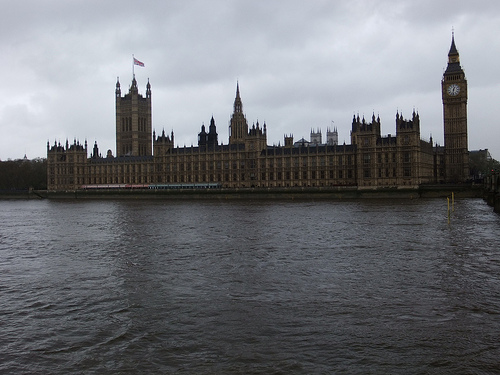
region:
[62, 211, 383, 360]
a body of water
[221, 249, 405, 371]
a body of calm water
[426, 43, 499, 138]
an outside clock on building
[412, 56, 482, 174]
a clock on a building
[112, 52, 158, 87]
a flag at the top of the buiding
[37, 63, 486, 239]
a long building along the water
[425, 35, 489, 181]
a brick building with clock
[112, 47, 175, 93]
a flag flying in the wind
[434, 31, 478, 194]
a tower at the end of the building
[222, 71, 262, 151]
a tower with a pointy spot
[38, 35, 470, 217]
a large castle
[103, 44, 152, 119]
a flag and flag pole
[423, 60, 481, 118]
a tower with a clock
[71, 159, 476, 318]
a body of water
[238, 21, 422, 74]
grey clouds in the sky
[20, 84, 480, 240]
a large building next to water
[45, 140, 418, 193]
a building with several windows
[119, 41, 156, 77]
a flag on a pole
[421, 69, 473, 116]
a white clock with black numbers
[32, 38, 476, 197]
a castle with a flag on top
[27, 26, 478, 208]
this is in london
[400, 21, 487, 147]
this is big ben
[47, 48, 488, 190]
big ben and the houses of parliment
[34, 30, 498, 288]
parliament seen from the thames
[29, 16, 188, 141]
the flag is flying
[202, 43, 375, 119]
the sky is overcast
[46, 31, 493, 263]
a grey london day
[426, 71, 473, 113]
the clock face is white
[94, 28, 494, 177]
a tourist photo of london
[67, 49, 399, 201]
the houses of parliament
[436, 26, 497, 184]
clock tower on the water front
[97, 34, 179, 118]
flag flying over a tower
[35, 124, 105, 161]
spires on the top of a building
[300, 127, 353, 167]
building towers with spires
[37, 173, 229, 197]
train on the water front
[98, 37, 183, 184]
tall tower with a flag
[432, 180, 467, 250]
poles in the water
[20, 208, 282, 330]
deep murky water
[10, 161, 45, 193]
dead trees near the building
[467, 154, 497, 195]
bridge across the water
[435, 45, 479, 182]
a brown tower clock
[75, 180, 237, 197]
a train on the tracks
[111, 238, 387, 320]
the water is dark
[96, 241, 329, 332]
the color of the water is brown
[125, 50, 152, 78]
a flag waiving in the air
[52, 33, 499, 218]
a large castle building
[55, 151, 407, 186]
the building has many windows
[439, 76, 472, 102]
the clock is round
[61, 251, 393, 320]
the water is calm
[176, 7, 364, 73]
the sky is dark and gloomy